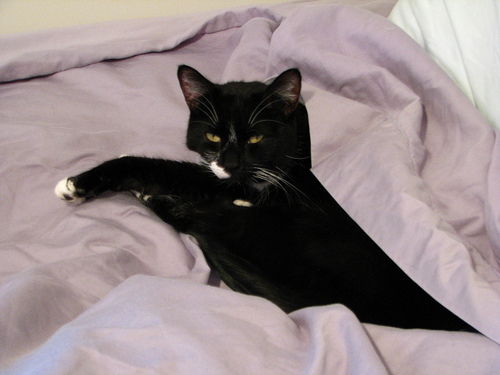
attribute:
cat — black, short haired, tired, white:
[54, 62, 479, 334]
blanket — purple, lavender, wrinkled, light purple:
[1, 3, 499, 373]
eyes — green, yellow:
[202, 128, 265, 146]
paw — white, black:
[51, 170, 99, 206]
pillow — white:
[387, 1, 499, 132]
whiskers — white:
[248, 160, 321, 213]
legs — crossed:
[49, 154, 222, 238]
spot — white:
[209, 160, 231, 179]